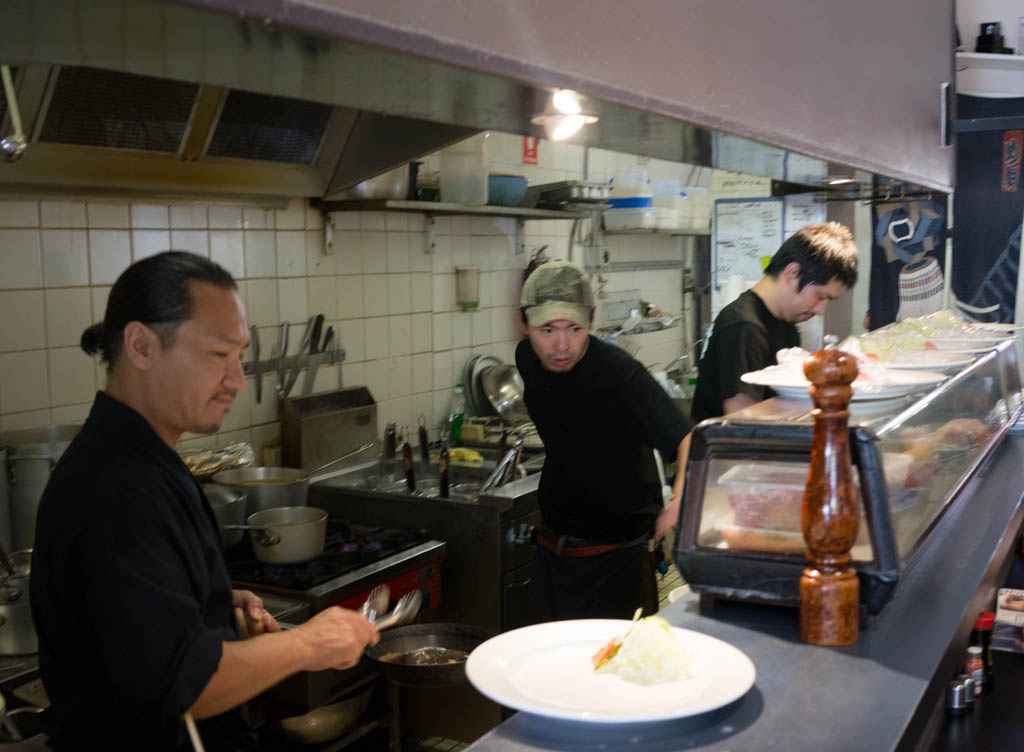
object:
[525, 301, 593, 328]
bill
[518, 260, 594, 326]
baseball cap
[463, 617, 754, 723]
plate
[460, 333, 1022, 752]
counte